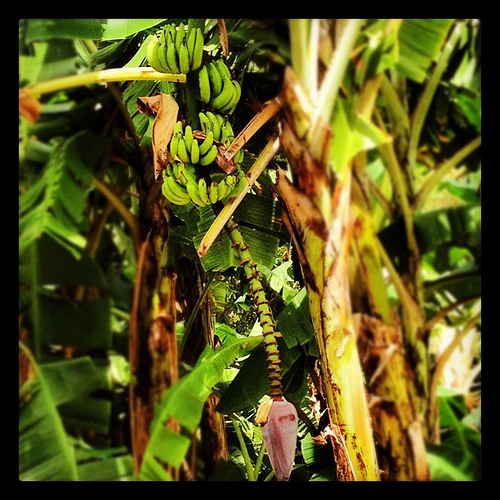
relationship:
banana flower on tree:
[253, 398, 297, 479] [119, 108, 296, 482]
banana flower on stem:
[253, 399, 297, 482] [189, 182, 357, 354]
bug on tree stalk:
[238, 292, 278, 321] [275, 120, 381, 482]